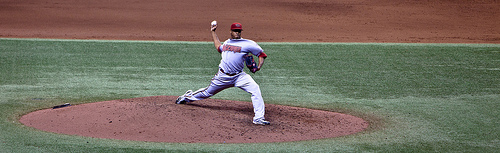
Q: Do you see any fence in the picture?
A: No, there are no fences.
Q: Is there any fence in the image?
A: No, there are no fences.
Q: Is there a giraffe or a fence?
A: No, there are no fences or giraffes.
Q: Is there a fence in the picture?
A: No, there are no fences.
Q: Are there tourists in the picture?
A: No, there are no tourists.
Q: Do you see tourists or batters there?
A: No, there are no tourists or batters.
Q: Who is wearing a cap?
A: The man is wearing a cap.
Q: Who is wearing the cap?
A: The man is wearing a cap.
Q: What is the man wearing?
A: The man is wearing a cap.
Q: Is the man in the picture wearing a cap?
A: Yes, the man is wearing a cap.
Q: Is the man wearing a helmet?
A: No, the man is wearing a cap.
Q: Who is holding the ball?
A: The man is holding the ball.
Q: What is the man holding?
A: The man is holding the ball.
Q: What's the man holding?
A: The man is holding the ball.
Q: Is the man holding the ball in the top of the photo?
A: Yes, the man is holding the ball.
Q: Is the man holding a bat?
A: No, the man is holding the ball.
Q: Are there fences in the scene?
A: No, there are no fences.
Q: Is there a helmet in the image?
A: No, there are no helmets.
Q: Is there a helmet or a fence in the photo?
A: No, there are no helmets or fences.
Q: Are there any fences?
A: No, there are no fences.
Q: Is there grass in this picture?
A: Yes, there is grass.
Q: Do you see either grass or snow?
A: Yes, there is grass.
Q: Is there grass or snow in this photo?
A: Yes, there is grass.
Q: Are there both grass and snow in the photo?
A: No, there is grass but no snow.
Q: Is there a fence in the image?
A: No, there are no fences.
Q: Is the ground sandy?
A: Yes, the ground is sandy.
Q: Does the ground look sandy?
A: Yes, the ground is sandy.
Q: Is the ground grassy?
A: No, the ground is sandy.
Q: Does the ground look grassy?
A: No, the ground is sandy.